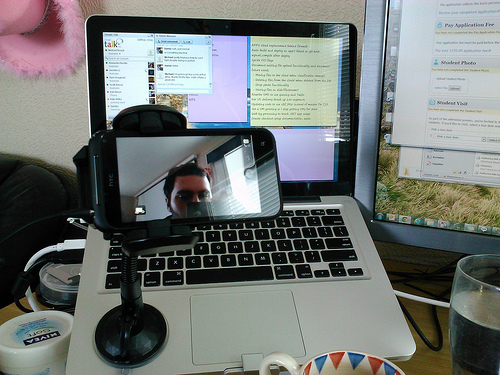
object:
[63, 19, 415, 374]
computer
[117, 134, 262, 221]
screen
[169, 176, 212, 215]
face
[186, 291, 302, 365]
touchpad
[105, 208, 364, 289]
keyboard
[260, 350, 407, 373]
mug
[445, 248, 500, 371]
glass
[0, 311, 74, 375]
container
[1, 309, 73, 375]
niveacream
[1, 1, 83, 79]
hat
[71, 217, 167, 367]
stand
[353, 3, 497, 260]
monitor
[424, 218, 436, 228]
programs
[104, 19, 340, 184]
screen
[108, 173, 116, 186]
htc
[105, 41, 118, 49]
googletalk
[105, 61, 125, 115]
contactlist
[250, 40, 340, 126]
sitcikynote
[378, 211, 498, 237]
taskbar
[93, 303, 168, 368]
base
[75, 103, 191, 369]
standhand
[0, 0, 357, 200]
plasterwall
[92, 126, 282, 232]
smartphone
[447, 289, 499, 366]
water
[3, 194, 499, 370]
desk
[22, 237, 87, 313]
cord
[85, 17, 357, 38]
frame